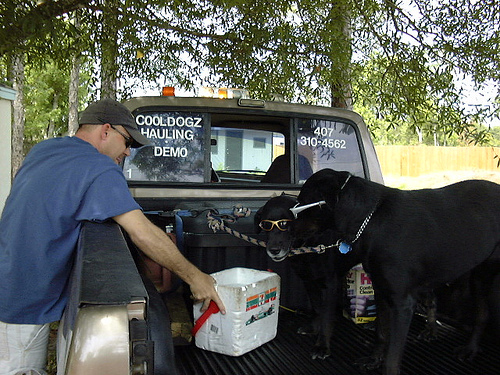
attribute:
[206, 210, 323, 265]
leash — green , white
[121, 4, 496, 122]
sky — blue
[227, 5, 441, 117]
tree — lacy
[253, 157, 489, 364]
dogs — tethered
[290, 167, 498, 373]
dog — gold 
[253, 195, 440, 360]
black dog — black , large 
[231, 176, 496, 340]
dogs — black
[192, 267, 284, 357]
cooler — white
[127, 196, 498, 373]
bed — open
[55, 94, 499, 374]
truck — open bed pickup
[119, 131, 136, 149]
sunglasses — black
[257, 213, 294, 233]
sunglasses — gold 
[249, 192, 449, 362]
dog — black 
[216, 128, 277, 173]
house — white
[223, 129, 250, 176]
door — black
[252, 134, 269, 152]
window — black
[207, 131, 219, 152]
window — black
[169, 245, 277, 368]
cooler — no top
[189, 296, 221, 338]
handle — red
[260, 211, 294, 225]
glasses — white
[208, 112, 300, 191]
window — open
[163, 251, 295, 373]
cooler — WHITE, FOAM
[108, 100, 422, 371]
truck — black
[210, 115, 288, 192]
rear window — open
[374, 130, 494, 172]
fence — wooden